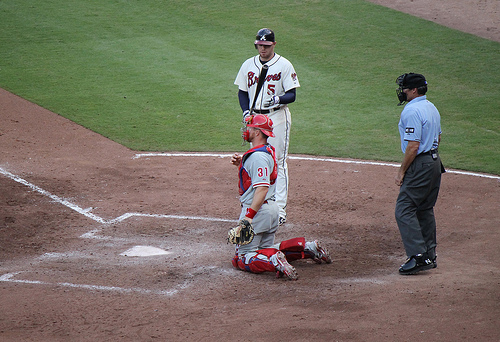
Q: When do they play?
A: Day time.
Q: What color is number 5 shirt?
A: White.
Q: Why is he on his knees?
A: To catch the pitch.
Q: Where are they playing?
A: Baseball field.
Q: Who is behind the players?
A: Umpire.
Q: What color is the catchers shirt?
A: Gray.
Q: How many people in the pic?
A: 3.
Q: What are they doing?
A: Playing baseball.